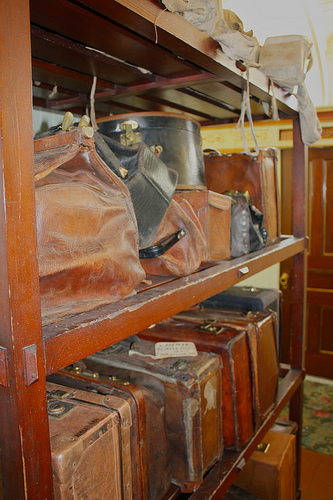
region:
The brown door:
[278, 308, 332, 371]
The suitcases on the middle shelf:
[40, 308, 269, 492]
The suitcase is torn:
[105, 342, 237, 474]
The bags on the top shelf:
[40, 102, 275, 260]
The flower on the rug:
[313, 403, 330, 422]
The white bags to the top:
[156, 3, 330, 125]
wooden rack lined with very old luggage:
[3, 1, 314, 494]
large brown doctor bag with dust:
[35, 108, 149, 319]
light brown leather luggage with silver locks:
[46, 375, 138, 493]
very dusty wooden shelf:
[47, 230, 298, 369]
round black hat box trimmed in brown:
[52, 107, 209, 189]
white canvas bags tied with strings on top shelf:
[141, 0, 319, 163]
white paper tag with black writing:
[136, 335, 196, 363]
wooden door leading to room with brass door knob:
[275, 147, 332, 373]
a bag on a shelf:
[22, 118, 186, 341]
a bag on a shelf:
[142, 179, 200, 266]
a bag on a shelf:
[93, 110, 179, 199]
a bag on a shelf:
[221, 183, 259, 250]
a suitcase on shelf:
[45, 392, 128, 490]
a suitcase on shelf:
[99, 378, 177, 478]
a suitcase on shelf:
[153, 312, 269, 439]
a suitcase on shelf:
[222, 307, 303, 433]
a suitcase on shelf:
[243, 431, 323, 492]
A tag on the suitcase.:
[144, 338, 198, 358]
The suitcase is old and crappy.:
[110, 337, 231, 486]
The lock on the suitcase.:
[195, 315, 225, 336]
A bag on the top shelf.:
[38, 118, 145, 300]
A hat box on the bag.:
[100, 109, 225, 192]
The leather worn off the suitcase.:
[176, 397, 203, 480]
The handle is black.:
[142, 233, 185, 257]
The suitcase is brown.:
[152, 312, 265, 466]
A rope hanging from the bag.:
[243, 58, 261, 165]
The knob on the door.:
[277, 258, 293, 292]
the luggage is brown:
[30, 126, 146, 312]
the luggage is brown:
[143, 186, 206, 272]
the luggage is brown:
[209, 151, 278, 254]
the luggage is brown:
[54, 365, 141, 497]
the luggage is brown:
[84, 339, 224, 492]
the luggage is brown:
[134, 310, 277, 450]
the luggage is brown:
[227, 435, 295, 498]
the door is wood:
[275, 148, 331, 379]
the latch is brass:
[255, 441, 269, 451]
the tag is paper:
[155, 338, 194, 358]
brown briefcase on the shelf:
[255, 433, 303, 492]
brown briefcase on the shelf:
[155, 340, 231, 478]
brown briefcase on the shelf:
[105, 366, 186, 490]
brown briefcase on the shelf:
[209, 326, 254, 450]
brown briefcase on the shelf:
[237, 307, 285, 416]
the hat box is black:
[53, 111, 207, 190]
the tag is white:
[154, 339, 196, 358]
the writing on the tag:
[155, 340, 198, 357]